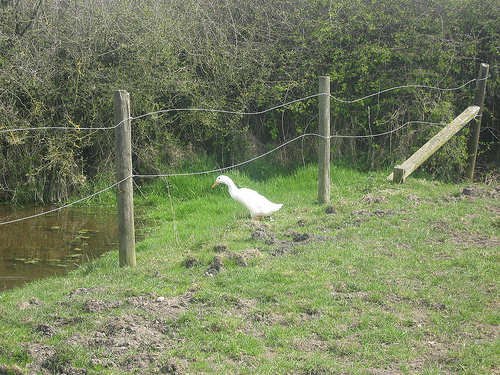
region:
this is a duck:
[203, 150, 308, 250]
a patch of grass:
[121, 280, 232, 357]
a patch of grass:
[238, 286, 290, 339]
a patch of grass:
[307, 310, 347, 366]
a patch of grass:
[171, 231, 301, 348]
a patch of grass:
[323, 190, 398, 287]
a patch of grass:
[236, 289, 306, 364]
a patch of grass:
[381, 289, 423, 343]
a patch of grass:
[222, 310, 280, 360]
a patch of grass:
[373, 303, 449, 373]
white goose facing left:
[208, 160, 280, 223]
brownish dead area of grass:
[118, 326, 179, 360]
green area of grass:
[395, 267, 445, 319]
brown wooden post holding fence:
[113, 112, 154, 282]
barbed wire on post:
[29, 124, 92, 150]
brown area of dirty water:
[20, 231, 57, 245]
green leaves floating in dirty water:
[27, 252, 79, 269]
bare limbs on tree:
[85, 8, 137, 32]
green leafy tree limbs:
[332, 54, 382, 92]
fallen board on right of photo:
[373, 95, 496, 209]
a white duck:
[201, 163, 300, 232]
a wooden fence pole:
[106, 83, 149, 277]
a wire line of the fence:
[3, 125, 119, 132]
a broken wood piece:
[383, 95, 483, 195]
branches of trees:
[10, 27, 491, 94]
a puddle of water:
[6, 192, 132, 283]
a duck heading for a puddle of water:
[1, 142, 319, 287]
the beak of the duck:
[210, 175, 218, 186]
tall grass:
[147, 152, 209, 213]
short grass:
[299, 246, 499, 372]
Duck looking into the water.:
[210, 160, 287, 232]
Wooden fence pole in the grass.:
[104, 77, 143, 277]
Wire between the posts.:
[141, 90, 320, 148]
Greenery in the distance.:
[333, 25, 384, 89]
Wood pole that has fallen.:
[390, 101, 479, 192]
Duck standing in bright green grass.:
[195, 155, 280, 224]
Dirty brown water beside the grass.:
[20, 210, 100, 280]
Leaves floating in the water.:
[35, 210, 102, 276]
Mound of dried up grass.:
[52, 305, 169, 363]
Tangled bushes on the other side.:
[13, 49, 139, 104]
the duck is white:
[183, 149, 308, 250]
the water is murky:
[14, 196, 110, 290]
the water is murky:
[20, 175, 152, 274]